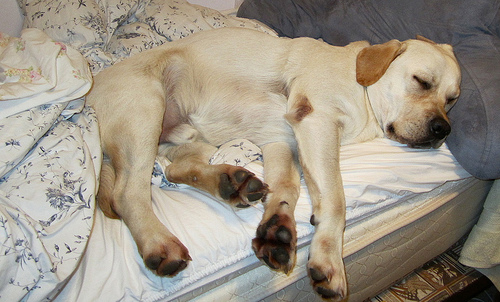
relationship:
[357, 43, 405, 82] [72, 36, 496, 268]
ear of dog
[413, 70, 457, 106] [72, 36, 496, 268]
eyes of dog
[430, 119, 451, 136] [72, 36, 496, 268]
nose of dog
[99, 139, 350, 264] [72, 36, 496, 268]
legs of dog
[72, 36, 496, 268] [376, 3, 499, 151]
dog on pillow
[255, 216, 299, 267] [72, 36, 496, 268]
paw of dog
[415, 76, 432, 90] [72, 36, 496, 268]
eye of dog